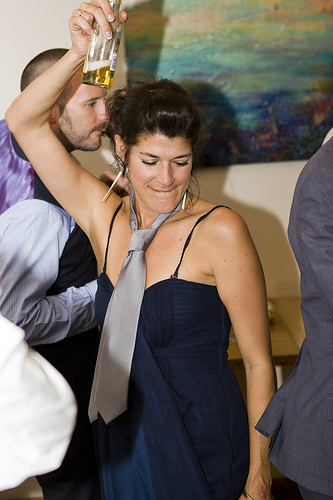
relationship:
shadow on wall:
[115, 5, 177, 90] [2, 1, 331, 284]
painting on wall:
[114, 1, 328, 171] [109, 3, 332, 163]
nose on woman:
[155, 163, 174, 188] [10, 46, 286, 457]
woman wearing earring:
[2, 0, 280, 500] [86, 116, 143, 240]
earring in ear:
[86, 116, 143, 240] [108, 129, 130, 167]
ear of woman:
[108, 129, 130, 167] [2, 0, 280, 500]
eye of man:
[83, 95, 99, 110] [16, 47, 114, 145]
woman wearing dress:
[25, 28, 311, 425] [39, 191, 261, 497]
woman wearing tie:
[2, 0, 280, 500] [119, 218, 167, 286]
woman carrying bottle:
[2, 0, 280, 500] [86, 16, 115, 88]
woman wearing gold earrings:
[2, 0, 280, 500] [96, 166, 189, 213]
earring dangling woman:
[100, 153, 129, 204] [5, 0, 271, 426]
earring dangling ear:
[100, 153, 129, 204] [111, 132, 124, 165]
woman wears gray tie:
[2, 0, 280, 500] [85, 176, 187, 425]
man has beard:
[8, 49, 118, 212] [56, 113, 100, 152]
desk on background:
[223, 293, 305, 405] [225, 302, 301, 374]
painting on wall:
[122, 1, 333, 168] [119, 0, 332, 131]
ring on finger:
[75, 10, 83, 16] [69, 7, 95, 26]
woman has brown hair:
[2, 0, 280, 500] [118, 78, 206, 141]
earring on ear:
[100, 153, 129, 204] [108, 131, 126, 163]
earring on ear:
[100, 153, 129, 204] [113, 134, 127, 162]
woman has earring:
[2, 0, 280, 500] [100, 153, 129, 204]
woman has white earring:
[2, 0, 280, 500] [100, 162, 129, 205]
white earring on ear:
[100, 162, 129, 205] [112, 132, 128, 162]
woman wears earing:
[2, 0, 280, 500] [179, 190, 186, 213]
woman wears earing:
[2, 0, 280, 500] [104, 166, 127, 204]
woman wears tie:
[2, 0, 280, 500] [115, 176, 192, 254]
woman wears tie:
[2, 0, 280, 500] [82, 175, 208, 409]